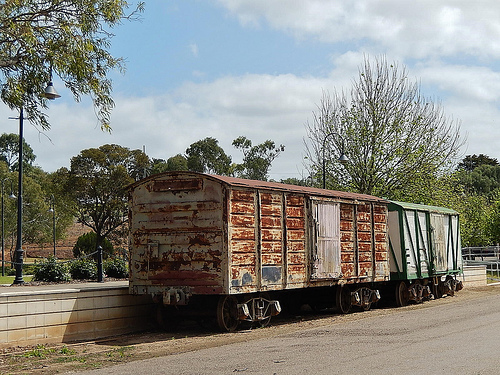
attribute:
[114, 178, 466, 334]
train — a wall, old, rusted, green, white, parked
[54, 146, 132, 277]
tree — green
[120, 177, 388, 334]
box car — old, rusty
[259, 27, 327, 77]
sky — bright, cloud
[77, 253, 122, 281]
grass — dried